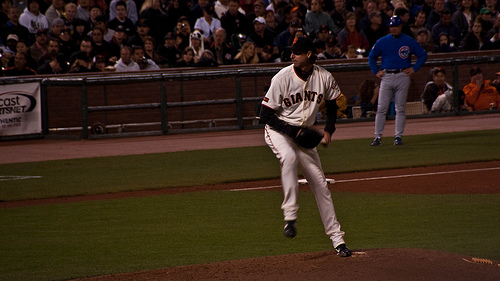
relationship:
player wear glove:
[258, 35, 353, 257] [294, 128, 323, 151]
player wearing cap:
[258, 35, 353, 257] [286, 36, 315, 55]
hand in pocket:
[405, 66, 414, 75] [401, 70, 412, 84]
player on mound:
[258, 35, 353, 257] [69, 246, 498, 280]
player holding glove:
[258, 35, 353, 257] [294, 128, 323, 151]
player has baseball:
[258, 35, 353, 257] [318, 137, 328, 146]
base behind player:
[295, 176, 337, 186] [258, 35, 353, 257]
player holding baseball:
[258, 35, 353, 257] [322, 134, 328, 147]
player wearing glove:
[258, 35, 353, 257] [294, 128, 323, 151]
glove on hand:
[294, 128, 323, 151] [405, 66, 414, 75]